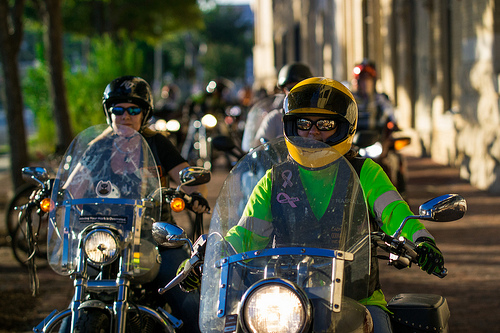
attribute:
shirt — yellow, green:
[225, 157, 431, 314]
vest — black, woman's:
[267, 157, 379, 299]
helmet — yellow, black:
[282, 75, 359, 170]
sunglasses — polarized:
[294, 118, 341, 132]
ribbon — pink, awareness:
[282, 168, 294, 188]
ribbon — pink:
[277, 192, 299, 208]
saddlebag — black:
[388, 293, 452, 333]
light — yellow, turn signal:
[172, 198, 184, 210]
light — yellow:
[40, 198, 54, 211]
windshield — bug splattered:
[199, 135, 370, 332]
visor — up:
[284, 83, 357, 127]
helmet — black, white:
[103, 78, 153, 118]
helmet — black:
[277, 65, 312, 89]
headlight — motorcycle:
[237, 278, 312, 333]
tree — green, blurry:
[0, 0, 202, 196]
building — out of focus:
[251, 2, 294, 93]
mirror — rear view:
[420, 194, 467, 221]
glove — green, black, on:
[413, 239, 445, 275]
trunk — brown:
[1, 3, 35, 191]